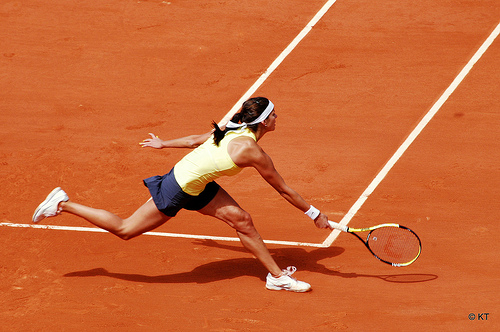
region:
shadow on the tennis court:
[180, 244, 238, 294]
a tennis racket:
[353, 221, 418, 267]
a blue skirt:
[150, 175, 184, 208]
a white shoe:
[34, 188, 65, 229]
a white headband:
[264, 99, 271, 113]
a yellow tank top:
[185, 151, 232, 172]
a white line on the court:
[413, 108, 443, 133]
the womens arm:
[135, 130, 196, 152]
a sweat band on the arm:
[300, 203, 319, 220]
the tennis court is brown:
[25, 14, 122, 88]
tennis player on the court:
[2, 71, 452, 318]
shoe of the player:
[261, 263, 313, 295]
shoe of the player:
[33, 181, 68, 221]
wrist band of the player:
[305, 206, 322, 225]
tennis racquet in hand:
[319, 201, 422, 276]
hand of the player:
[144, 132, 169, 158]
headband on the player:
[264, 103, 281, 130]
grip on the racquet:
[336, 220, 356, 237]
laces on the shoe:
[288, 262, 303, 279]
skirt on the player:
[152, 173, 214, 214]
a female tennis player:
[31, 98, 331, 291]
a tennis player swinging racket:
[31, 95, 423, 293]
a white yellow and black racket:
[326, 218, 421, 268]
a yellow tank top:
[171, 129, 254, 196]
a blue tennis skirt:
[142, 165, 220, 218]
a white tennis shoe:
[265, 272, 311, 291]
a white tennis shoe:
[31, 185, 68, 222]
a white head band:
[246, 98, 274, 127]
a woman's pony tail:
[209, 110, 239, 145]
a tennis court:
[0, 1, 498, 249]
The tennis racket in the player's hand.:
[320, 208, 429, 265]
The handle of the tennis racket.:
[320, 215, 352, 240]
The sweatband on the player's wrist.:
[300, 204, 322, 220]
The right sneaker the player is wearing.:
[270, 274, 313, 296]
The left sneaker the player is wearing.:
[31, 187, 68, 218]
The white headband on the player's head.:
[246, 95, 271, 122]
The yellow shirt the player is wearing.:
[178, 131, 273, 194]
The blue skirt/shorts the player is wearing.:
[140, 170, 225, 215]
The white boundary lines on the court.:
[5, 2, 493, 239]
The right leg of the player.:
[220, 183, 290, 284]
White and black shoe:
[9, 171, 95, 243]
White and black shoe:
[254, 261, 317, 303]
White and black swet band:
[293, 193, 325, 228]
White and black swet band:
[221, 98, 283, 129]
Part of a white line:
[390, 130, 444, 154]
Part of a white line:
[410, 50, 486, 94]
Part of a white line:
[284, 11, 321, 48]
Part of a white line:
[0, 185, 82, 254]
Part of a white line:
[165, 216, 237, 259]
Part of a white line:
[269, 225, 349, 253]